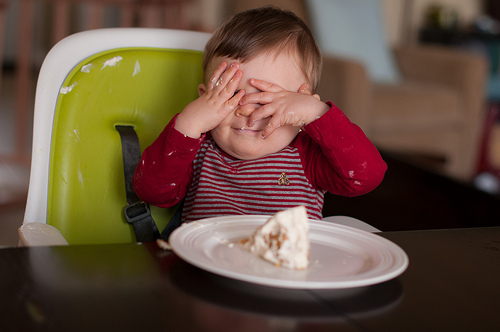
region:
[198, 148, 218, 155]
red stripe on shirt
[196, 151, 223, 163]
red stripe on shirt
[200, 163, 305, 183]
red stripe on shirt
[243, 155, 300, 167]
red stripe on shirt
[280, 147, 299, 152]
red stripe on shirt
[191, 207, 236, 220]
red stripe on shirt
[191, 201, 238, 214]
red stripe on shirt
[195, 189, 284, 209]
red stripe on shirt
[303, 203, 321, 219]
red stripe on shirt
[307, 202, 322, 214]
red stripe on shirt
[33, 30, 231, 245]
The green high chair.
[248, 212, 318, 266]
The cake on the plate.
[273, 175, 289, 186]
The bear logo on the shirt.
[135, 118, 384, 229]
The red long sleeved shirt.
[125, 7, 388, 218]
The baby covering their eyes.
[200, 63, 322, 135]
The babys hands.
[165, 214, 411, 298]
The white plate on the table.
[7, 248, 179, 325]
The black table.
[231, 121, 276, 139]
The baby mouth.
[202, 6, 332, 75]
The brown hair on the baby.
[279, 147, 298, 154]
red strip on shirt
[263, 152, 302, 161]
red strip on shirt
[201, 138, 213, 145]
red strip on shirt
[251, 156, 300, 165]
red strip on shirt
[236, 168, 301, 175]
red strip on shirt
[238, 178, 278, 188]
red strip on shirt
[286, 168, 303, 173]
red strip on shirt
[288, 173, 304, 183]
red strip on shirt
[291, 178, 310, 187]
red strip on shirt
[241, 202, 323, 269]
cake kept in the cake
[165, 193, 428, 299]
white color circle shape of the plate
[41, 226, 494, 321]
brown color wooden table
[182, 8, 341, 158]
head of the baby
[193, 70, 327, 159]
a baby hiding its eyes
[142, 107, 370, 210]
a baby wearing red color full hand shirt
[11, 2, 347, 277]
baby is sitting with the green and white color chair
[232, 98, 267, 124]
nose of the baby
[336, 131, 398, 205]
elbow of the baby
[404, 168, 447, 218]
brown color floor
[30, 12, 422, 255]
little kid sitting in a highchair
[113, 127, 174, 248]
black strap on the highchair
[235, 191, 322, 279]
piece of food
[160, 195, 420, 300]
food on a plate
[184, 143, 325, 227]
red and gray stripes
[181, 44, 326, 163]
hands on the face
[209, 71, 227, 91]
food on the fingers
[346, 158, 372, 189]
food stain on the shirt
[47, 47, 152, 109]
food smeared on the chair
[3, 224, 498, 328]
dark brown wood on the tabletop